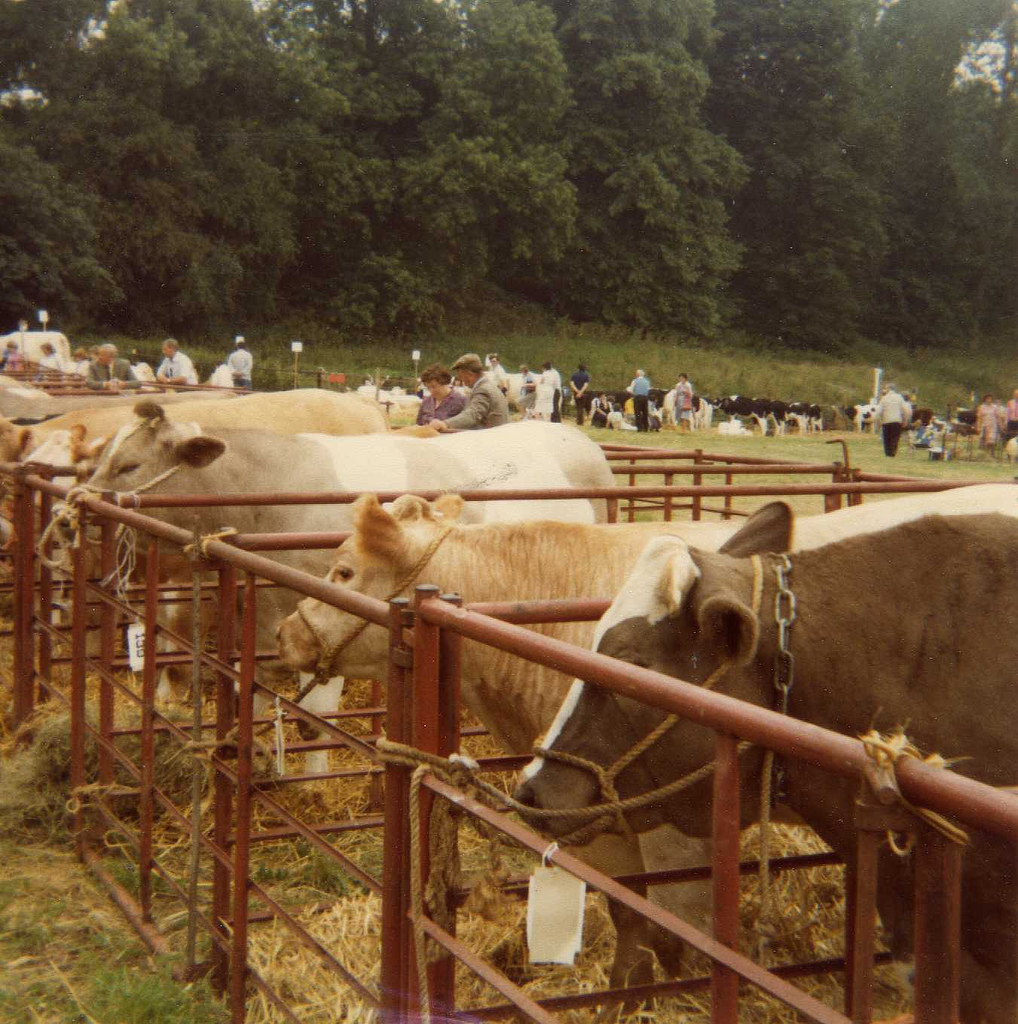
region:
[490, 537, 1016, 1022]
The cow is standing by the cage.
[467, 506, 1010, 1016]
The cow is a dark brown with a white spot on his face.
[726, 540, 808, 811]
The cow has a chain around his neck.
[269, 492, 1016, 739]
The cow is standing by the fence.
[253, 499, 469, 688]
The cow has a rope around his face.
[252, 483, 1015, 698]
The cow is a light brown.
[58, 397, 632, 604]
The cow is standing by the fence.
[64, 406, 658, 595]
The cow is brown and white.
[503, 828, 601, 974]
There is a white tag hanging from the fence.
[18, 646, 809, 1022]
There is hay on the ground under the cows.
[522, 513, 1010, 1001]
the cow is brown and white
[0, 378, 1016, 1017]
the cows are in a row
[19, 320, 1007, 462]
the people are standing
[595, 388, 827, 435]
the cows are white and black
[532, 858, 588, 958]
the cage has a tag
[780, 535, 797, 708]
the cow has a chain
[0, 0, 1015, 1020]
the scene takes place outdoors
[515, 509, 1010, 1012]
a brown and white cow is in a pen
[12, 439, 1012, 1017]
the pens are made of metal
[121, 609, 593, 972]
tags are hanging from the pens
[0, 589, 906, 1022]
hay is strewn underneath the cows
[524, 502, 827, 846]
the cow has a chain around its neck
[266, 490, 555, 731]
the cow has a rope halter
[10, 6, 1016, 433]
tall green trees are behind the crowd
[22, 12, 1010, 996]
a scene at a farm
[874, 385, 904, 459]
A person is standing up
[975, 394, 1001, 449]
A person is standing up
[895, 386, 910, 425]
A person is standing up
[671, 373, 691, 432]
A person is standing up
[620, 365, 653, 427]
A person is standing up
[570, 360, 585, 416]
A person is standing up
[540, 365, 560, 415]
A person is standing up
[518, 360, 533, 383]
A person is standing up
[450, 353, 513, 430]
A person is standing up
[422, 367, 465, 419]
A person is standing up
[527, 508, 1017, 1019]
cow is black and white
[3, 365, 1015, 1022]
red cattle panels are holding the cows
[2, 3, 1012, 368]
trees on the hill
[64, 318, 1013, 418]
grass on the hill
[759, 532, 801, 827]
chain collar on the cow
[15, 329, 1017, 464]
people all here viewing cattle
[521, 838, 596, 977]
tag for this cow identification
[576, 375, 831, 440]
black and white dairy cows in the distance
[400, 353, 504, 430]
two people viewing cattle in the pens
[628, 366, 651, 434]
A person is standing up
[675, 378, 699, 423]
A person is standing up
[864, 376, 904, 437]
A person is standing up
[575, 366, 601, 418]
A person is standing up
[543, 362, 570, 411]
A person is standing up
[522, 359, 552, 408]
A person is standing up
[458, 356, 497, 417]
A person is standing up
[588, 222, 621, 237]
green leaves on the tree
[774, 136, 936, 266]
green leaves on the tree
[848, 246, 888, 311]
green leaves on the tree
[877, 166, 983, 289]
green leaves on the tree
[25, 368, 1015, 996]
Livestock in metal pens.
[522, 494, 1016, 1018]
cow standing in a cage in the field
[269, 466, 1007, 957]
cow standing in a cage in the field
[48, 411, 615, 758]
cow standing in a cage in the field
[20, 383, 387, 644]
cow standing in a cage in the field